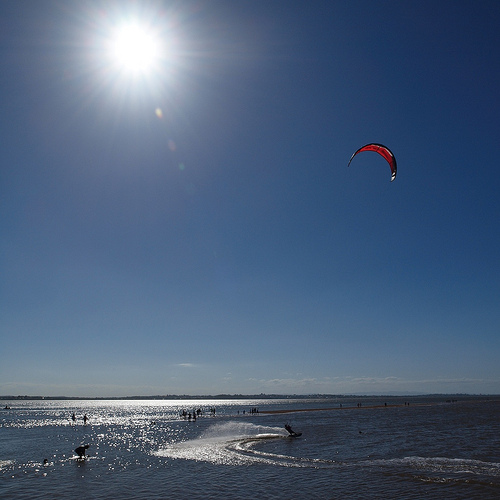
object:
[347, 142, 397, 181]
parasailer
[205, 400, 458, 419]
sand barge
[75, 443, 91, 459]
person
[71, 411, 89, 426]
people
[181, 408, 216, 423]
people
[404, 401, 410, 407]
people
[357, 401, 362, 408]
people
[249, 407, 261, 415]
people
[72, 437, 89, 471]
person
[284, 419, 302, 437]
person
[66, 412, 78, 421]
person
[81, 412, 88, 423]
person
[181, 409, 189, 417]
person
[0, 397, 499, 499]
water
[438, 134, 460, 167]
ground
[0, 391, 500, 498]
beach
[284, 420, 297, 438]
man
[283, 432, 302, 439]
surfboard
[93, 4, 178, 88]
sun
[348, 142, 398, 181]
kite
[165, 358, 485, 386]
clouds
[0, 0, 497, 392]
sky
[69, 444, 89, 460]
person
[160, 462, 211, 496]
waves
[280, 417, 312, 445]
person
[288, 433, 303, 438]
board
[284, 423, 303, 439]
people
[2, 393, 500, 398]
horizon